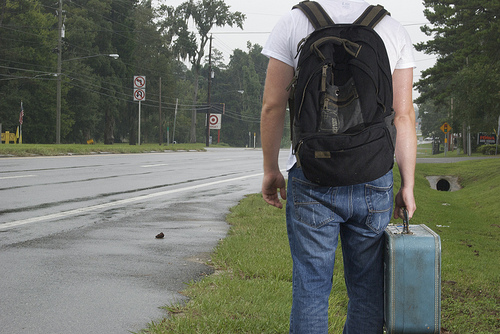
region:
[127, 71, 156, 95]
sign with red circle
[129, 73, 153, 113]
signs with white backgrounds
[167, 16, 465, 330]
person on side of road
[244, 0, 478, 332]
person carrying blue suitcase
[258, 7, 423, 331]
person wearing blue jeans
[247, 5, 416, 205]
black backpack on back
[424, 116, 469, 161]
street light notice sign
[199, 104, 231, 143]
red bullseye sign on white background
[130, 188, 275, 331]
green grass on side of road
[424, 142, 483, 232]
driveway culvert in grass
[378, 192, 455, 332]
green weathered suitcase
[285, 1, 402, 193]
black back pack worn over the shoulders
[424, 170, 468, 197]
grey cement drainage pipe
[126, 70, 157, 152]
red, white, and black traffic signs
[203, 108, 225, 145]
red and white target sign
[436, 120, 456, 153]
yellow diamond shaped warning traffic sign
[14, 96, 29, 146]
red, white, and blue american flag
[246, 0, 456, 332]
man wearing a white shirt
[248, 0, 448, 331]
man wearing blue jeans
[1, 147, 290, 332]
empty grey and white road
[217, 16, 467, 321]
person with backpack and luggage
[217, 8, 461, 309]
guy with backpack and luggage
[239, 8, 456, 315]
man with backpack and luggage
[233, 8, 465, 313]
male with backpack and luggage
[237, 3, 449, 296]
person outside with backpack and luggage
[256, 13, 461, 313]
person waiting with backpack and luggage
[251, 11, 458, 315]
person standing with backpack and luggage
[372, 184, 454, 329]
hand holding a suitcase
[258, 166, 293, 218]
left hand of a person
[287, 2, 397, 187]
black backpack on a person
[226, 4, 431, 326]
man in tee shirt and jeans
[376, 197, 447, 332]
blue suitcase in hand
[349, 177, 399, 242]
back pocket of blue jeans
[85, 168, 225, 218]
white line on side of road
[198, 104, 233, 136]
logo on store sign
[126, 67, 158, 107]
warning signs for traffic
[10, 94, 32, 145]
American flag on pole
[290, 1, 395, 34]
backpack straps on shoulders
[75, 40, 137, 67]
street light on post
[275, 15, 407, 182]
The backpak the person is wearing.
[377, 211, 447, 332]
A blue suitcase the person is holding.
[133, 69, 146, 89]
A no left turn sign.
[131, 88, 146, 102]
A no u-turn sign.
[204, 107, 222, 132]
A sign for Target.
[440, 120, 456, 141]
A sign for a traffic light.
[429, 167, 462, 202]
A drainage pipe.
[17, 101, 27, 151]
An American flag.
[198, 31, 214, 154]
A telephone pole.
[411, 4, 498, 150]
A tree with green leaves.